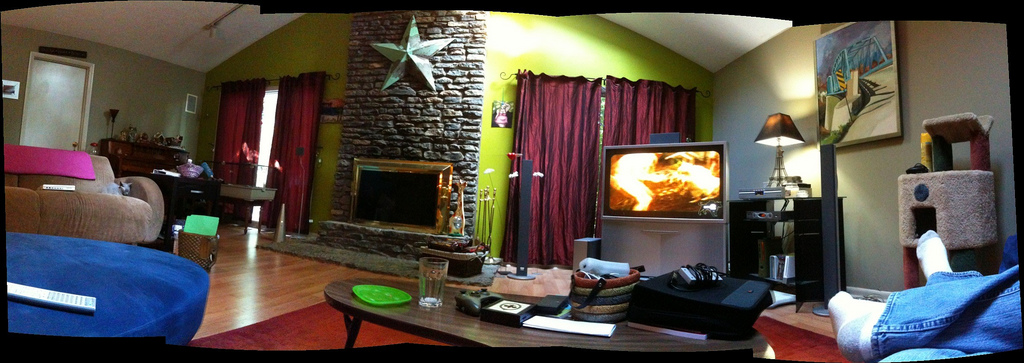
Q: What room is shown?
A: It is a living room.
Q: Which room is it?
A: It is a living room.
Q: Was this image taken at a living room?
A: Yes, it was taken in a living room.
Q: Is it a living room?
A: Yes, it is a living room.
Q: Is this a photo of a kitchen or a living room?
A: It is showing a living room.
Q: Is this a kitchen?
A: No, it is a living room.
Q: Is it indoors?
A: Yes, it is indoors.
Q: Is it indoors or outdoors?
A: It is indoors.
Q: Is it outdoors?
A: No, it is indoors.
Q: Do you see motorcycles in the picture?
A: No, there are no motorcycles.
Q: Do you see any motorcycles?
A: No, there are no motorcycles.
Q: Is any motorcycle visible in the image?
A: No, there are no motorcycles.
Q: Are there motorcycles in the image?
A: No, there are no motorcycles.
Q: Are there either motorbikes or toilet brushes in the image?
A: No, there are no motorbikes or toilet brushes.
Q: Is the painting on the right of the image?
A: Yes, the painting is on the right of the image.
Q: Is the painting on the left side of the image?
A: No, the painting is on the right of the image.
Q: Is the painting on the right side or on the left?
A: The painting is on the right of the image.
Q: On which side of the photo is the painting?
A: The painting is on the right of the image.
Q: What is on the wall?
A: The painting is on the wall.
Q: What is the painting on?
A: The painting is on the wall.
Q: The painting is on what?
A: The painting is on the wall.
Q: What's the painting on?
A: The painting is on the wall.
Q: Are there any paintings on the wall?
A: Yes, there is a painting on the wall.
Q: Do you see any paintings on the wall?
A: Yes, there is a painting on the wall.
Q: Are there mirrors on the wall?
A: No, there is a painting on the wall.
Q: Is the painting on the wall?
A: Yes, the painting is on the wall.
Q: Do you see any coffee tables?
A: Yes, there is a coffee table.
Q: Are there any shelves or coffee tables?
A: Yes, there is a coffee table.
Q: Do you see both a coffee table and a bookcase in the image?
A: No, there is a coffee table but no bookcases.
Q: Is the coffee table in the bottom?
A: Yes, the coffee table is in the bottom of the image.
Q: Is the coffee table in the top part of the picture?
A: No, the coffee table is in the bottom of the image.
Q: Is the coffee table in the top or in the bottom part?
A: The coffee table is in the bottom of the image.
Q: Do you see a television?
A: Yes, there is a television.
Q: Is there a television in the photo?
A: Yes, there is a television.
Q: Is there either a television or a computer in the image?
A: Yes, there is a television.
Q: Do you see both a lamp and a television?
A: Yes, there are both a television and a lamp.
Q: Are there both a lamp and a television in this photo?
A: Yes, there are both a television and a lamp.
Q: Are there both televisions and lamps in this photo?
A: Yes, there are both a television and a lamp.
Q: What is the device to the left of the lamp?
A: The device is a television.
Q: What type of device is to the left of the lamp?
A: The device is a television.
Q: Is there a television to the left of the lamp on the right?
A: Yes, there is a television to the left of the lamp.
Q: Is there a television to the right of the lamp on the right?
A: No, the television is to the left of the lamp.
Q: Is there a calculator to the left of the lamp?
A: No, there is a television to the left of the lamp.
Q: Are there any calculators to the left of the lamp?
A: No, there is a television to the left of the lamp.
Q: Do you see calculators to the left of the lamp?
A: No, there is a television to the left of the lamp.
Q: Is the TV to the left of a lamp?
A: Yes, the TV is to the left of a lamp.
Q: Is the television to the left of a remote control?
A: No, the television is to the left of a lamp.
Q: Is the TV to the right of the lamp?
A: No, the TV is to the left of the lamp.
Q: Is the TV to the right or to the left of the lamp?
A: The TV is to the left of the lamp.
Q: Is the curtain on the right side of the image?
A: No, the curtain is on the left of the image.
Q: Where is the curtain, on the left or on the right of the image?
A: The curtain is on the left of the image.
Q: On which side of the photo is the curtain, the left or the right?
A: The curtain is on the left of the image.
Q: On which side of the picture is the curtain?
A: The curtain is on the left of the image.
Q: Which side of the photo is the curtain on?
A: The curtain is on the left of the image.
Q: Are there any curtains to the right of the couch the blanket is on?
A: Yes, there is a curtain to the right of the couch.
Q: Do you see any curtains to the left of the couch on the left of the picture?
A: No, the curtain is to the right of the couch.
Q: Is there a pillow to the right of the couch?
A: No, there is a curtain to the right of the couch.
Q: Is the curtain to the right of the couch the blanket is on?
A: Yes, the curtain is to the right of the couch.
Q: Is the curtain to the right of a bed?
A: No, the curtain is to the right of the couch.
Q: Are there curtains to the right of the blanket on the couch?
A: Yes, there is a curtain to the right of the blanket.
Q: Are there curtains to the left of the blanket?
A: No, the curtain is to the right of the blanket.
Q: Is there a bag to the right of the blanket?
A: No, there is a curtain to the right of the blanket.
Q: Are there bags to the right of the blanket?
A: No, there is a curtain to the right of the blanket.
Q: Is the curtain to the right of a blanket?
A: Yes, the curtain is to the right of a blanket.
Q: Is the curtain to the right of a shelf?
A: No, the curtain is to the right of a blanket.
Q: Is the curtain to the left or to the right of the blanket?
A: The curtain is to the right of the blanket.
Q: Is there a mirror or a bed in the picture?
A: No, there are no beds or mirrors.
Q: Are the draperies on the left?
A: Yes, the draperies are on the left of the image.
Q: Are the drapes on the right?
A: No, the drapes are on the left of the image.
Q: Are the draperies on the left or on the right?
A: The draperies are on the left of the image.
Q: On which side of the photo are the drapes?
A: The drapes are on the left of the image.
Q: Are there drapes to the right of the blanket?
A: Yes, there are drapes to the right of the blanket.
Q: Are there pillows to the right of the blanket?
A: No, there are drapes to the right of the blanket.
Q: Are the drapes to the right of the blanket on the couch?
A: Yes, the drapes are to the right of the blanket.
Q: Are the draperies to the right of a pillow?
A: No, the draperies are to the right of the blanket.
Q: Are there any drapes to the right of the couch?
A: Yes, there are drapes to the right of the couch.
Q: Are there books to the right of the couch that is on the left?
A: No, there are drapes to the right of the couch.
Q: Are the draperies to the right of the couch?
A: Yes, the draperies are to the right of the couch.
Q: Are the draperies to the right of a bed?
A: No, the draperies are to the right of the couch.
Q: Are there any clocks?
A: No, there are no clocks.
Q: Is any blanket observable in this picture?
A: Yes, there is a blanket.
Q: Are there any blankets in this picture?
A: Yes, there is a blanket.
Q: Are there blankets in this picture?
A: Yes, there is a blanket.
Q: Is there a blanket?
A: Yes, there is a blanket.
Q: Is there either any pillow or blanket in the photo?
A: Yes, there is a blanket.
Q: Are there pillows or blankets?
A: Yes, there is a blanket.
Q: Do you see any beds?
A: No, there are no beds.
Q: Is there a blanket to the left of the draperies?
A: Yes, there is a blanket to the left of the draperies.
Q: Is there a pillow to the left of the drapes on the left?
A: No, there is a blanket to the left of the draperies.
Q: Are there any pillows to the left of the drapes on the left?
A: No, there is a blanket to the left of the draperies.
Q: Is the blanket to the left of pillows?
A: No, the blanket is to the left of the drapes.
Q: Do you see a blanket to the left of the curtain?
A: Yes, there is a blanket to the left of the curtain.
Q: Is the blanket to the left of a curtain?
A: Yes, the blanket is to the left of a curtain.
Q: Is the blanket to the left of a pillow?
A: No, the blanket is to the left of a curtain.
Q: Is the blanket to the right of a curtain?
A: No, the blanket is to the left of a curtain.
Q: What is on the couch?
A: The blanket is on the couch.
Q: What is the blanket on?
A: The blanket is on the couch.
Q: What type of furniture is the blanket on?
A: The blanket is on the couch.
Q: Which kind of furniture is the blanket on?
A: The blanket is on the couch.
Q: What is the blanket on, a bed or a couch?
A: The blanket is on a couch.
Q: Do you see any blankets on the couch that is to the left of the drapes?
A: Yes, there is a blanket on the couch.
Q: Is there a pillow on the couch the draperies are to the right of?
A: No, there is a blanket on the couch.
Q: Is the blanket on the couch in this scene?
A: Yes, the blanket is on the couch.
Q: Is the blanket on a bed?
A: No, the blanket is on the couch.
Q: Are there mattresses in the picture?
A: No, there are no mattresses.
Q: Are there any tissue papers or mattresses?
A: No, there are no mattresses or tissue papers.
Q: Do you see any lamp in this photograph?
A: Yes, there is a lamp.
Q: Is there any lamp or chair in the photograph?
A: Yes, there is a lamp.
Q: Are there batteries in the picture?
A: No, there are no batteries.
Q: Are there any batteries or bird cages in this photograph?
A: No, there are no batteries or bird cages.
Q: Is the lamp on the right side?
A: Yes, the lamp is on the right of the image.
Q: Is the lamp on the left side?
A: No, the lamp is on the right of the image.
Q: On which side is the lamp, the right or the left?
A: The lamp is on the right of the image.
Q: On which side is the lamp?
A: The lamp is on the right of the image.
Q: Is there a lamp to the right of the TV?
A: Yes, there is a lamp to the right of the TV.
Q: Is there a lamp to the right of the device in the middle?
A: Yes, there is a lamp to the right of the TV.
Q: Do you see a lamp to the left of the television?
A: No, the lamp is to the right of the television.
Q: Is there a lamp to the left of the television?
A: No, the lamp is to the right of the television.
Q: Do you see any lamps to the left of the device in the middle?
A: No, the lamp is to the right of the television.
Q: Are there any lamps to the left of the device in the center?
A: No, the lamp is to the right of the television.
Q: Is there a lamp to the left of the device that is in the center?
A: No, the lamp is to the right of the television.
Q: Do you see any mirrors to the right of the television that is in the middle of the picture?
A: No, there is a lamp to the right of the TV.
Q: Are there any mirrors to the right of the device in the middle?
A: No, there is a lamp to the right of the TV.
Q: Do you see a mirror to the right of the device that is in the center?
A: No, there is a lamp to the right of the TV.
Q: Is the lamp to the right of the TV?
A: Yes, the lamp is to the right of the TV.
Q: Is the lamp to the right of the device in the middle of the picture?
A: Yes, the lamp is to the right of the TV.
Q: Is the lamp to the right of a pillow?
A: No, the lamp is to the right of the TV.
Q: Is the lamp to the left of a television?
A: No, the lamp is to the right of a television.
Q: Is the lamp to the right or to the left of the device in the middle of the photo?
A: The lamp is to the right of the TV.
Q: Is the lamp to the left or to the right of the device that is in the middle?
A: The lamp is to the right of the TV.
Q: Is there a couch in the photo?
A: Yes, there is a couch.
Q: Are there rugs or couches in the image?
A: Yes, there is a couch.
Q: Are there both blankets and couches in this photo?
A: Yes, there are both a couch and a blanket.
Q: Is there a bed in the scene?
A: No, there are no beds.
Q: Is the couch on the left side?
A: Yes, the couch is on the left of the image.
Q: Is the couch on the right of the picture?
A: No, the couch is on the left of the image.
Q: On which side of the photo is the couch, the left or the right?
A: The couch is on the left of the image.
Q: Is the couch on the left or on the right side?
A: The couch is on the left of the image.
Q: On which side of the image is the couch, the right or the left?
A: The couch is on the left of the image.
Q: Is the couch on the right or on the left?
A: The couch is on the left of the image.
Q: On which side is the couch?
A: The couch is on the left of the image.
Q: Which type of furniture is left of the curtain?
A: The piece of furniture is a couch.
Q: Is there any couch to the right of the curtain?
A: No, the couch is to the left of the curtain.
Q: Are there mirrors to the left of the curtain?
A: No, there is a couch to the left of the curtain.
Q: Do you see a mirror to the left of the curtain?
A: No, there is a couch to the left of the curtain.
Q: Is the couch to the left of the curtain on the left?
A: Yes, the couch is to the left of the curtain.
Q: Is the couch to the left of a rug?
A: No, the couch is to the left of the curtain.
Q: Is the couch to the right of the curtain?
A: No, the couch is to the left of the curtain.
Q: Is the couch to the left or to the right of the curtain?
A: The couch is to the left of the curtain.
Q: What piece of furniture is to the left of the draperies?
A: The piece of furniture is a couch.